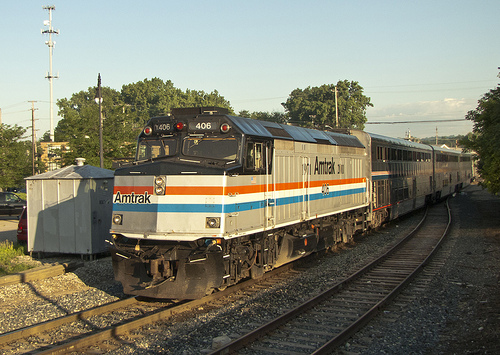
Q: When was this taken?
A: Daytime.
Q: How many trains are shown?
A: 1.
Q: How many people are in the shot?
A: 0.